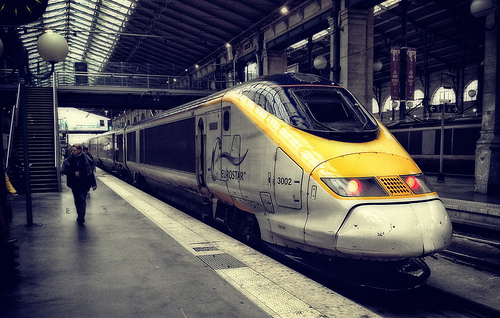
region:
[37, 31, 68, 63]
the white globe light of the station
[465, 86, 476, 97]
the white globe light of the station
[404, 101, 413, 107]
the white globe light of the station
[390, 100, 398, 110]
the white globe light of the station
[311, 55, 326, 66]
the white globe light of the station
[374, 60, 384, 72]
the white globe light of the station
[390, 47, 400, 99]
the red and white banner flag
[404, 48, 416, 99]
the red and white banner flag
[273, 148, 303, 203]
the small door of the train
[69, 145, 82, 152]
the head of the person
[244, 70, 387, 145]
FRONT WINDSHIELD OF YELLOW TRAIN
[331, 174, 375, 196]
HEADLIGHT OF YELLOW TRAIN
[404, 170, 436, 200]
HEADLIGHT OF YELLOW TRAIN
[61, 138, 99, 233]
PERSON WALKING ON TRAIN PLATFORM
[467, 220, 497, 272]
PART OF TRAIN TRACKS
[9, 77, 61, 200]
STAIRWAY NEAR TRAIN TRACKS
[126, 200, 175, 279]
PART OF TRAIN PLATFORM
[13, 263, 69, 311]
PART OF TRAIN PLATFORM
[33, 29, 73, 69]
HANGING LIGHT ABOVE PLATFORM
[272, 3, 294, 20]
HANGING LIGHT ABOVE PLATFORM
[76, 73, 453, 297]
a white and yellow train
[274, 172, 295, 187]
the number 3002 on a train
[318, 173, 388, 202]
the headlight on a train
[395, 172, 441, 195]
the headlight on a train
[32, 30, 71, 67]
a lamp on a pole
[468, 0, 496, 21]
a lamp on a pole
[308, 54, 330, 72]
a lamp on a pole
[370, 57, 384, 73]
a lamp on a pole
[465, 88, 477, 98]
a lamp on a pole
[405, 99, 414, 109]
a lamp on a pole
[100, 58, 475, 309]
large train at train station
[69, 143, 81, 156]
the head of the person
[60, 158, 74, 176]
the arm of the person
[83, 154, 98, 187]
the arm of the person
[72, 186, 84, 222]
the leg of the person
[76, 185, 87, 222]
the leg of the person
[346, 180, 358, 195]
the bright orange headlight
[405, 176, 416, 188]
the bright orange headlight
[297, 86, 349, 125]
the big window of the train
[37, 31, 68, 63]
the white ball of light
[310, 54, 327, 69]
the white ball of light